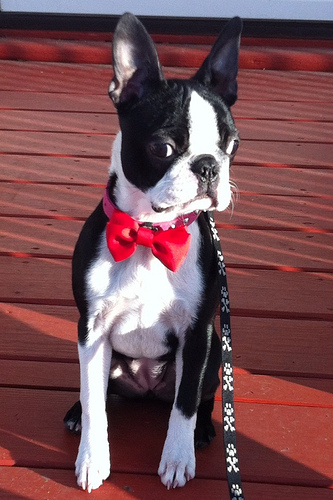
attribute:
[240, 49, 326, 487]
floor — wooden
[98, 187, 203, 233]
collar — red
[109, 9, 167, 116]
ear — pointed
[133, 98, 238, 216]
face — black, white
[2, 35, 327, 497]
deck — wooden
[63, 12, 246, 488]
dog — black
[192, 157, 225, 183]
nose — Black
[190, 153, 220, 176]
nose — black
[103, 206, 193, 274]
bowtie — red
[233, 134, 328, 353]
floor — red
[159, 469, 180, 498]
nails — short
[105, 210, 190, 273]
tie — red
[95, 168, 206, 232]
dog's collar — red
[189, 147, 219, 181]
nose — black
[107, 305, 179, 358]
chest — white